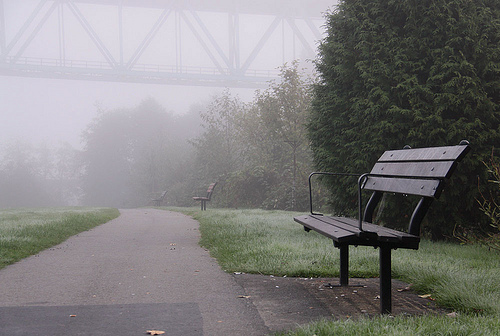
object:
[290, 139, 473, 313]
bench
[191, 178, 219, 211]
bench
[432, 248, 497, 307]
grass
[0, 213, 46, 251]
grass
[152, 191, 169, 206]
bench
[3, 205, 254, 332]
road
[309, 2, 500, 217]
bush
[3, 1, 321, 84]
bridge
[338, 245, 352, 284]
leg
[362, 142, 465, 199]
backplate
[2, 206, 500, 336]
ground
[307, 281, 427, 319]
brick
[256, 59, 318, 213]
tree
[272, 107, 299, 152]
branch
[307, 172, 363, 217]
armrest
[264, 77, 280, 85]
leaves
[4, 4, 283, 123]
sky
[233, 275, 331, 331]
cement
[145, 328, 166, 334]
leaf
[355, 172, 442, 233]
armrest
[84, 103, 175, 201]
foliage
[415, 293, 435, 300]
leaf